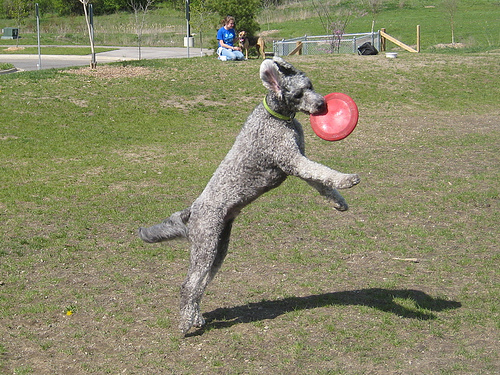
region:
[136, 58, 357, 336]
a gray dog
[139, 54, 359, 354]
a gray dog jumping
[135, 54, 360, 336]
a gray dog with a frisbee in its mouth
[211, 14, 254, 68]
woman with dog sitting on the ground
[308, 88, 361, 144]
a red frisbee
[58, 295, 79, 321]
yellow flower in the dirt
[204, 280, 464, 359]
dogs shadow on the ground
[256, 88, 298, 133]
yellow collar around the dogs neck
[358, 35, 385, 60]
black bag next to a fence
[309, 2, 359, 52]
purple flowers within the fencing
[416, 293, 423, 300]
part of a shadow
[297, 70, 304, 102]
face of a dog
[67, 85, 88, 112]
part of a fence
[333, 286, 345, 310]
part of a shadow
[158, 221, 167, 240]
part of a tail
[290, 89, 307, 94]
eye of a dog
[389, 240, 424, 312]
part of a shadow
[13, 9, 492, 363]
a dog park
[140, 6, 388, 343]
dogs in a park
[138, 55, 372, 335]
a dog catching a Frisbee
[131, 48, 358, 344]
the dog jumps in the air to catch a frisbee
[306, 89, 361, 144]
the frisbee is red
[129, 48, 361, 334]
the dog is catching a red frisbee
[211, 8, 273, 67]
a woman kneels next to a dog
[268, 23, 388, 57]
a metal fence surrounds a small tree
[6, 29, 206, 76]
a parking area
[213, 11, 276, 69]
a woman with a dog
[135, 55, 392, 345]
dog with frisbee in mouth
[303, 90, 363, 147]
red frisbee in dog's mouth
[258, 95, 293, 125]
yellow collar on dog's neck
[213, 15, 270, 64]
woman with dog in back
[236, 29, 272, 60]
dog next to woman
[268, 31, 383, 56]
enclosed fence area near woman and dog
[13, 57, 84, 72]
concrete area in park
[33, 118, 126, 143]
grassy area in park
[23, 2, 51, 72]
sign in concrete area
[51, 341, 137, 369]
barer area with little grass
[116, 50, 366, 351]
a dog holding a Frisbee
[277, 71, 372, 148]
a red Frisbee in the mouth of dog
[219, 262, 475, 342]
shadow cast on the ground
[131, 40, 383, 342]
dog stand in two feet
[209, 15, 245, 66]
woman wears blue shirt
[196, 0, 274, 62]
a bush behind a woman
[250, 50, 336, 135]
dog has agreen collar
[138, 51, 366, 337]
color of dog is salt and pepper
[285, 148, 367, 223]
front legs of dog